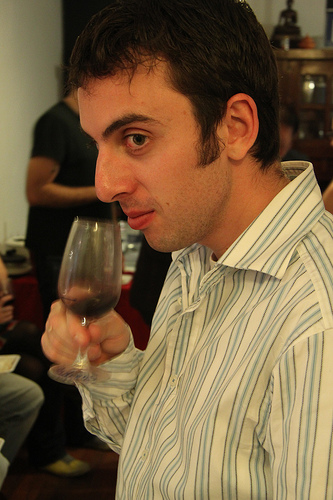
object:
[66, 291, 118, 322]
dark liquid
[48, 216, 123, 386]
wine glass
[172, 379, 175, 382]
blue string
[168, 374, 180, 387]
white button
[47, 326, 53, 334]
gold ring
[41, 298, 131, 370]
right hand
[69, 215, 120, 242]
blurry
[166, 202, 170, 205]
mole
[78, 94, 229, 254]
man's face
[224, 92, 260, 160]
ear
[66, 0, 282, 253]
man's head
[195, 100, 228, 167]
sideburn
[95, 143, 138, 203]
nose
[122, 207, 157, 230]
lips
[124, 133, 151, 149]
left eye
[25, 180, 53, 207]
elbow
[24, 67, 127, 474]
woman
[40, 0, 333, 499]
man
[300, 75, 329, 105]
shakers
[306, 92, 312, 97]
stainless steel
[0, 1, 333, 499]
background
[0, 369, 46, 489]
grey pants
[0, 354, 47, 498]
man in background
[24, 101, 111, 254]
black shirt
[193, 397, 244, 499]
striped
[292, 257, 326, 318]
stripes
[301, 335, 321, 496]
blue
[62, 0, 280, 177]
hair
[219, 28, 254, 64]
brown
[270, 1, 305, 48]
buddha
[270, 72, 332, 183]
mantle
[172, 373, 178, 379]
white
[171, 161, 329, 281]
shirt collar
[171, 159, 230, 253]
down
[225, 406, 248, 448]
black,blue & white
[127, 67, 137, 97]
strand of hair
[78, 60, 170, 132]
forehead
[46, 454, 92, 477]
shoe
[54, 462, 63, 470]
bright yellow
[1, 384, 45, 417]
long wrinkles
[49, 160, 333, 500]
shirt